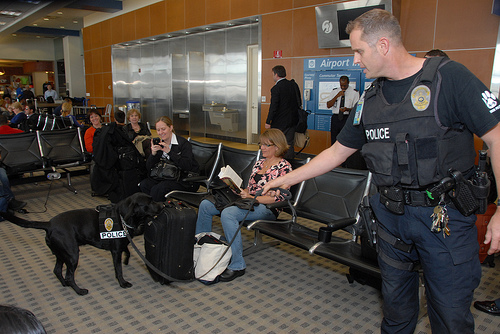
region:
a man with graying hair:
[344, 8, 412, 78]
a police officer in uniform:
[283, 10, 497, 326]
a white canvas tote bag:
[190, 225, 239, 287]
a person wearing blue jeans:
[195, 195, 268, 267]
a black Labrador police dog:
[11, 190, 162, 297]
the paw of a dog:
[119, 275, 131, 288]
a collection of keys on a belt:
[432, 181, 457, 238]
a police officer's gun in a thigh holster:
[345, 195, 417, 272]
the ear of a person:
[379, 38, 390, 53]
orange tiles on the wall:
[113, 0, 209, 43]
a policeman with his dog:
[6, 10, 497, 330]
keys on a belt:
[417, 185, 466, 245]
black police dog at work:
[3, 184, 250, 304]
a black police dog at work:
[2, 172, 204, 298]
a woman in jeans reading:
[172, 120, 316, 287]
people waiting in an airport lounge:
[0, 35, 97, 191]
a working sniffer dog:
[2, 175, 192, 302]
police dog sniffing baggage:
[2, 165, 199, 300]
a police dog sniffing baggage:
[0, 135, 172, 299]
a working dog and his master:
[3, 3, 498, 331]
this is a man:
[331, 13, 458, 315]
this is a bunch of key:
[430, 205, 462, 245]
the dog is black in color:
[56, 220, 87, 254]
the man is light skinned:
[293, 160, 321, 185]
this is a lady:
[246, 110, 281, 192]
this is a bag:
[171, 203, 209, 290]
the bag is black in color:
[148, 219, 175, 254]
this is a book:
[216, 164, 247, 198]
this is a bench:
[302, 192, 337, 243]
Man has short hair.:
[363, 10, 398, 36]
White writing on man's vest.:
[356, 118, 401, 153]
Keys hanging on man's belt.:
[426, 198, 458, 238]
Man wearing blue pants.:
[406, 219, 467, 292]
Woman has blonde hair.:
[260, 129, 298, 158]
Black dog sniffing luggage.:
[61, 184, 132, 290]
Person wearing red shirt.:
[81, 123, 90, 146]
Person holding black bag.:
[152, 153, 199, 194]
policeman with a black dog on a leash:
[1, 15, 496, 326]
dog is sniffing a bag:
[3, 197, 205, 292]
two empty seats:
[0, 125, 86, 177]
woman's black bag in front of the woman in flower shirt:
[133, 195, 194, 280]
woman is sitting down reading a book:
[190, 130, 295, 266]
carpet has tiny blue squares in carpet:
[3, 143, 496, 329]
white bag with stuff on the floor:
[195, 228, 235, 281]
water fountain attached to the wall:
[200, 90, 243, 136]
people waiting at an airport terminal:
[3, 75, 483, 325]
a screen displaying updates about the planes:
[300, 5, 415, 48]